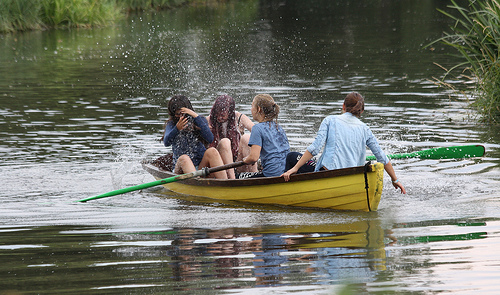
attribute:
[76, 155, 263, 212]
oar — green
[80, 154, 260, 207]
paddle — green, brown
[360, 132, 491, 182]
paddle — green, brown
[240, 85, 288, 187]
water — blue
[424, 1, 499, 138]
grass — green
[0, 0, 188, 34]
grass — green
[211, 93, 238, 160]
hair — long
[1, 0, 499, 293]
water — blue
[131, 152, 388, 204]
boat — yellow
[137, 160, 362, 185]
rail — brown, wood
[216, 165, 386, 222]
boat — yellow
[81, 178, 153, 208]
oar — green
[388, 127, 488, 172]
oar — green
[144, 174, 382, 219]
base — yellow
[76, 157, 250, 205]
oar — green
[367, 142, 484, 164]
oar — green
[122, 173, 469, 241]
water — splashing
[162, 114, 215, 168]
top — dark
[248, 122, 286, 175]
top — blue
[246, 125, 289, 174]
shirt — light blue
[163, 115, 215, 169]
shirt — dark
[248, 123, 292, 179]
shirt — gray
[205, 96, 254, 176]
girl — brown